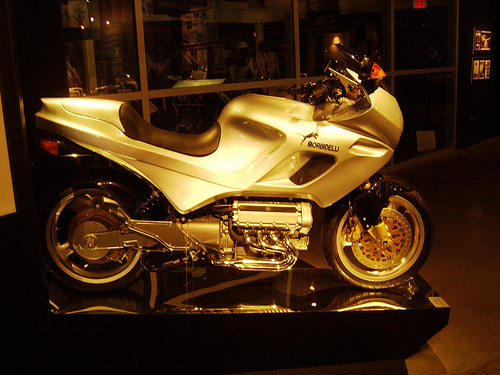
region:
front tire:
[325, 201, 437, 286]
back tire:
[49, 191, 131, 287]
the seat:
[127, 114, 217, 159]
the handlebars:
[305, 61, 350, 111]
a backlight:
[32, 134, 66, 159]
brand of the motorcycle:
[300, 130, 347, 155]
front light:
[367, 55, 392, 81]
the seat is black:
[124, 115, 216, 153]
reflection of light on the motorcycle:
[210, 140, 278, 170]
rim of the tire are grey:
[357, 260, 374, 280]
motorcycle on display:
[15, 61, 455, 318]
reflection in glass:
[164, 28, 291, 113]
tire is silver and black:
[333, 188, 434, 290]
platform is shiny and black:
[51, 298, 449, 363]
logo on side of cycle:
[303, 125, 351, 168]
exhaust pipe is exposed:
[193, 208, 313, 274]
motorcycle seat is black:
[113, 105, 229, 163]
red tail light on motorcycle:
[33, 136, 67, 163]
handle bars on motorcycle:
[291, 79, 357, 119]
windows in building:
[87, 5, 349, 77]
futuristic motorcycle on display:
[37, 27, 432, 294]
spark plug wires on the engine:
[212, 228, 298, 273]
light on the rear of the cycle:
[36, 137, 59, 154]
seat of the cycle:
[107, 96, 243, 160]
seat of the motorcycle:
[112, 92, 237, 160]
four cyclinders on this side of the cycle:
[219, 200, 311, 273]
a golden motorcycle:
[40, 39, 429, 289]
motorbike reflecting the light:
[36, 36, 431, 287]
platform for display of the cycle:
[29, 276, 449, 361]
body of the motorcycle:
[33, 87, 399, 214]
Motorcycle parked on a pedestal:
[38, 68, 435, 316]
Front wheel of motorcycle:
[312, 170, 441, 295]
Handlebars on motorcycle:
[302, 25, 384, 109]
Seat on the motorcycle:
[93, 78, 238, 175]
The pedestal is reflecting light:
[73, 275, 449, 362]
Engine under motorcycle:
[205, 189, 343, 298]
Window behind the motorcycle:
[71, 30, 267, 101]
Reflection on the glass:
[128, 43, 265, 94]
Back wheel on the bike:
[37, 180, 209, 330]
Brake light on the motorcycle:
[31, 125, 65, 162]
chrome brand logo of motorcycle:
[296, 128, 343, 160]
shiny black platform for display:
[29, 288, 466, 368]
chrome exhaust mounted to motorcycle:
[220, 222, 306, 297]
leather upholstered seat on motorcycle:
[107, 92, 230, 172]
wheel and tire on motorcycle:
[319, 168, 436, 296]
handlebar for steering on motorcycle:
[293, 47, 351, 109]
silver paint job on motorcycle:
[61, 106, 103, 134]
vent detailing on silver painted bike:
[271, 144, 351, 191]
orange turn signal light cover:
[27, 130, 77, 165]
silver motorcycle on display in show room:
[16, 47, 468, 353]